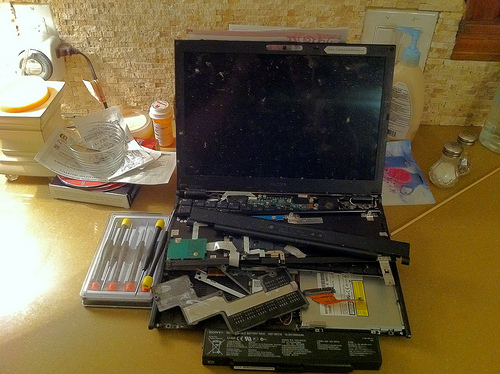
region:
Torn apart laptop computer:
[163, 41, 409, 336]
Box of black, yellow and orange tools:
[79, 211, 169, 307]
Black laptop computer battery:
[200, 325, 382, 372]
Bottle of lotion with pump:
[387, 23, 426, 146]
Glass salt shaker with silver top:
[427, 139, 462, 189]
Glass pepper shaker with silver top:
[454, 129, 476, 179]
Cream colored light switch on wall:
[360, 6, 439, 75]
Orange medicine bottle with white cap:
[147, 98, 174, 150]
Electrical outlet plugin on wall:
[2, 3, 70, 86]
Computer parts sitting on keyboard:
[148, 203, 414, 335]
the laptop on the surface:
[166, 33, 440, 361]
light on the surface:
[0, 192, 72, 332]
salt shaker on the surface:
[429, 141, 461, 193]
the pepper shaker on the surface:
[455, 128, 481, 185]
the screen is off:
[166, 44, 381, 206]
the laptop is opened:
[169, 203, 412, 343]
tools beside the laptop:
[81, 206, 162, 316]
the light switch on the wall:
[361, 8, 433, 69]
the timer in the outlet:
[4, 31, 79, 90]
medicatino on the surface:
[146, 91, 175, 153]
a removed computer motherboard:
[156, 267, 307, 331]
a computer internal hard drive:
[293, 267, 405, 332]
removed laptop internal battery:
[204, 330, 381, 371]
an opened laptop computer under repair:
[150, 36, 415, 368]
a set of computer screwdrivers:
[81, 212, 168, 304]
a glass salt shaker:
[430, 139, 460, 185]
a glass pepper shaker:
[456, 127, 476, 175]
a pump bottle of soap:
[388, 23, 427, 143]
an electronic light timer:
[12, 36, 67, 93]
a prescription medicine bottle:
[149, 100, 175, 147]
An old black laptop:
[161, 34, 394, 372]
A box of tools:
[101, 214, 158, 304]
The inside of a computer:
[207, 276, 323, 328]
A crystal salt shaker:
[430, 128, 463, 203]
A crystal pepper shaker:
[460, 122, 477, 177]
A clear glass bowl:
[71, 105, 133, 172]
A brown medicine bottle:
[142, 85, 179, 155]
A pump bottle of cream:
[384, 19, 440, 171]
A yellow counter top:
[428, 214, 491, 339]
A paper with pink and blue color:
[382, 145, 441, 212]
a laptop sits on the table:
[149, 19, 424, 366]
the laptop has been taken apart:
[153, 184, 419, 367]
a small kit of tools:
[76, 203, 156, 312]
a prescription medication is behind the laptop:
[138, 100, 174, 152]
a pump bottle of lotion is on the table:
[387, 20, 437, 144]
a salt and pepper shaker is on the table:
[428, 126, 478, 193]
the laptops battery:
[191, 321, 388, 372]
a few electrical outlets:
[8, 3, 81, 78]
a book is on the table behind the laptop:
[47, 129, 154, 216]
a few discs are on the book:
[61, 170, 126, 200]